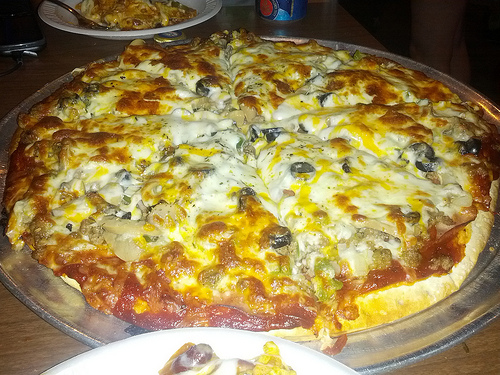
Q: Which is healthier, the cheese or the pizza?
A: The cheese is healthier than the pizza.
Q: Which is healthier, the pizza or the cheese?
A: The cheese is healthier than the pizza.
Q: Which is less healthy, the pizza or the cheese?
A: The pizza is less healthy than the cheese.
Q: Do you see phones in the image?
A: Yes, there is a phone.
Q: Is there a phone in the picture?
A: Yes, there is a phone.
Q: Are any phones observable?
A: Yes, there is a phone.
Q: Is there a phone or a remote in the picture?
A: Yes, there is a phone.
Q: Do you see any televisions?
A: No, there are no televisions.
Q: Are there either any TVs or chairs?
A: No, there are no TVs or chairs.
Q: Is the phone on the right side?
A: No, the phone is on the left of the image.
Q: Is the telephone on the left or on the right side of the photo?
A: The telephone is on the left of the image.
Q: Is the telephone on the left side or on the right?
A: The telephone is on the left of the image.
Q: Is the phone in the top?
A: Yes, the phone is in the top of the image.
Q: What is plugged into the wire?
A: The telephone is plugged into the wire.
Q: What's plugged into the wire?
A: The telephone is plugged into the wire.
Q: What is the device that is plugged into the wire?
A: The device is a phone.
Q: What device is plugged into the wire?
A: The device is a phone.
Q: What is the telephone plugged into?
A: The telephone is plugged into the wire.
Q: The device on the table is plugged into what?
A: The telephone is plugged into the wire.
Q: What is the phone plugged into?
A: The telephone is plugged into the wire.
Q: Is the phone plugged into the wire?
A: Yes, the phone is plugged into the wire.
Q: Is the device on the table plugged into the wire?
A: Yes, the phone is plugged into the wire.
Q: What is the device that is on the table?
A: The device is a phone.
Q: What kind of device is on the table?
A: The device is a phone.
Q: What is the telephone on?
A: The telephone is on the table.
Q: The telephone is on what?
A: The telephone is on the table.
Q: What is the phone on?
A: The telephone is on the table.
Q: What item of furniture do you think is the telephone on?
A: The telephone is on the table.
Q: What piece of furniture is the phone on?
A: The telephone is on the table.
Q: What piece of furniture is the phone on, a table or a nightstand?
A: The phone is on a table.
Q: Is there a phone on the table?
A: Yes, there is a phone on the table.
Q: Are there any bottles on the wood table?
A: No, there is a phone on the table.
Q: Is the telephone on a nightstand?
A: No, the telephone is on the table.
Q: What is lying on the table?
A: The phone is lying on the table.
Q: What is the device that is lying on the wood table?
A: The device is a phone.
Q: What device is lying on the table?
A: The device is a phone.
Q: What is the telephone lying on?
A: The telephone is lying on the table.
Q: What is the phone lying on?
A: The telephone is lying on the table.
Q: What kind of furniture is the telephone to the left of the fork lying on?
A: The telephone is lying on the table.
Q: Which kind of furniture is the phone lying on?
A: The telephone is lying on the table.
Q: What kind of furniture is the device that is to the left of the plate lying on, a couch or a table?
A: The phone is lying on a table.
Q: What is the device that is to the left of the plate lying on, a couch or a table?
A: The phone is lying on a table.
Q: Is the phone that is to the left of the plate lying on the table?
A: Yes, the telephone is lying on the table.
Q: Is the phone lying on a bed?
A: No, the phone is lying on the table.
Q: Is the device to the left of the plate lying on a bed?
A: No, the phone is lying on the table.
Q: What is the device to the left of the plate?
A: The device is a phone.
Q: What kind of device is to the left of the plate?
A: The device is a phone.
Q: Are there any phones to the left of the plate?
A: Yes, there is a phone to the left of the plate.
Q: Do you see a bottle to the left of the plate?
A: No, there is a phone to the left of the plate.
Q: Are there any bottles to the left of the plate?
A: No, there is a phone to the left of the plate.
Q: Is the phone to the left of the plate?
A: Yes, the phone is to the left of the plate.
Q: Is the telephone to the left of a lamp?
A: No, the telephone is to the left of the plate.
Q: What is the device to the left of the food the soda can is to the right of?
A: The device is a phone.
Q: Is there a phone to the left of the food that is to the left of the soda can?
A: Yes, there is a phone to the left of the food.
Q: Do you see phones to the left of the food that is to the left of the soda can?
A: Yes, there is a phone to the left of the food.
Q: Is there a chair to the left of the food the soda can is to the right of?
A: No, there is a phone to the left of the food.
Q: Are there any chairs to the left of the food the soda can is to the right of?
A: No, there is a phone to the left of the food.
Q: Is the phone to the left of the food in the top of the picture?
A: Yes, the phone is to the left of the food.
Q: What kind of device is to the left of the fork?
A: The device is a phone.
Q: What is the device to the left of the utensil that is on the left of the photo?
A: The device is a phone.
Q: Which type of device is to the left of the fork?
A: The device is a phone.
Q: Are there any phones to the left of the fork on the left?
A: Yes, there is a phone to the left of the fork.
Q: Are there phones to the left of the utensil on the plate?
A: Yes, there is a phone to the left of the fork.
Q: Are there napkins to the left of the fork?
A: No, there is a phone to the left of the fork.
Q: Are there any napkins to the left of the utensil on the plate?
A: No, there is a phone to the left of the fork.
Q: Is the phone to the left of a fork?
A: Yes, the phone is to the left of a fork.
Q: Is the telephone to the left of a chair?
A: No, the telephone is to the left of a fork.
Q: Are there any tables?
A: Yes, there is a table.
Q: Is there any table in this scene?
A: Yes, there is a table.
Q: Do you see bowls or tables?
A: Yes, there is a table.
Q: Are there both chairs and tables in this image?
A: No, there is a table but no chairs.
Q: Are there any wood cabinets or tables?
A: Yes, there is a wood table.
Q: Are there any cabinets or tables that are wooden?
A: Yes, the table is wooden.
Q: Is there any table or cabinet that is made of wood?
A: Yes, the table is made of wood.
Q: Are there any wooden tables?
A: Yes, there is a wood table.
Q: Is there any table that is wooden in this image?
A: Yes, there is a wood table.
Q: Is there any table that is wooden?
A: Yes, there is a table that is wooden.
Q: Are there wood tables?
A: Yes, there is a table that is made of wood.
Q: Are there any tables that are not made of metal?
A: Yes, there is a table that is made of wood.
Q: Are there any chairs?
A: No, there are no chairs.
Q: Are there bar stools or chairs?
A: No, there are no chairs or bar stools.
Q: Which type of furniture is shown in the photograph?
A: The furniture is a table.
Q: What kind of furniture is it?
A: The piece of furniture is a table.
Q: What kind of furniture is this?
A: That is a table.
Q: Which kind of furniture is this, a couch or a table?
A: That is a table.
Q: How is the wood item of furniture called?
A: The piece of furniture is a table.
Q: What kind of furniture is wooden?
A: The furniture is a table.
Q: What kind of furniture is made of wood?
A: The furniture is a table.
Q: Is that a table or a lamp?
A: That is a table.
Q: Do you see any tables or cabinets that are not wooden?
A: No, there is a table but it is wooden.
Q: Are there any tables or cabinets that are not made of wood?
A: No, there is a table but it is made of wood.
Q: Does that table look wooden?
A: Yes, the table is wooden.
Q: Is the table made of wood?
A: Yes, the table is made of wood.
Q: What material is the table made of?
A: The table is made of wood.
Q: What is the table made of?
A: The table is made of wood.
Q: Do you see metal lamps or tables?
A: No, there is a table but it is wooden.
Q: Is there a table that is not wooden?
A: No, there is a table but it is wooden.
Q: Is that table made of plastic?
A: No, the table is made of wood.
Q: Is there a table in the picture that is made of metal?
A: No, there is a table but it is made of wood.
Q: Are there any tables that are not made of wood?
A: No, there is a table but it is made of wood.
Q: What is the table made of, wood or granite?
A: The table is made of wood.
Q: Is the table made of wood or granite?
A: The table is made of wood.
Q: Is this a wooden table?
A: Yes, this is a wooden table.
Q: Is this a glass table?
A: No, this is a wooden table.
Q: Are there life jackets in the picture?
A: No, there are no life jackets.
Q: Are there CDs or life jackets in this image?
A: No, there are no life jackets or cds.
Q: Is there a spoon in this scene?
A: No, there are no spoons.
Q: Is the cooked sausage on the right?
A: Yes, the sausage is on the right of the image.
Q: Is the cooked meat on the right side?
A: Yes, the sausage is on the right of the image.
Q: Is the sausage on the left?
A: No, the sausage is on the right of the image.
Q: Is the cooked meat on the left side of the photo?
A: No, the sausage is on the right of the image.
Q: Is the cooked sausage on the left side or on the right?
A: The sausage is on the right of the image.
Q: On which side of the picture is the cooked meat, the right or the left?
A: The sausage is on the right of the image.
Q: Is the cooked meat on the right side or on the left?
A: The sausage is on the right of the image.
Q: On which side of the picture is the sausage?
A: The sausage is on the right of the image.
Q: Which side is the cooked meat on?
A: The sausage is on the right of the image.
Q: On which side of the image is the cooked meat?
A: The sausage is on the right of the image.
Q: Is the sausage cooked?
A: Yes, the sausage is cooked.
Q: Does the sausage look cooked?
A: Yes, the sausage is cooked.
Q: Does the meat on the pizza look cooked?
A: Yes, the sausage is cooked.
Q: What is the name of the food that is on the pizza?
A: The food is a sausage.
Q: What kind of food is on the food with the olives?
A: The food is a sausage.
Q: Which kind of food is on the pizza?
A: The food is a sausage.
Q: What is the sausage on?
A: The sausage is on the pizza.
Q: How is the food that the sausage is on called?
A: The food is a pizza.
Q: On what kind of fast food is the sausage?
A: The sausage is on the pizza.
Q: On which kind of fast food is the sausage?
A: The sausage is on the pizza.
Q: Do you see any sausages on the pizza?
A: Yes, there is a sausage on the pizza.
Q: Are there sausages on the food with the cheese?
A: Yes, there is a sausage on the pizza.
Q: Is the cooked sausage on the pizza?
A: Yes, the sausage is on the pizza.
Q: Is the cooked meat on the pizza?
A: Yes, the sausage is on the pizza.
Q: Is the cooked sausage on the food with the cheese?
A: Yes, the sausage is on the pizza.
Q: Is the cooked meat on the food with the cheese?
A: Yes, the sausage is on the pizza.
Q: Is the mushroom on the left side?
A: Yes, the mushroom is on the left of the image.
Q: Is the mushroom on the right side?
A: No, the mushroom is on the left of the image.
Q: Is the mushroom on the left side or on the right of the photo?
A: The mushroom is on the left of the image.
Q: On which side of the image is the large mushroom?
A: The mushroom is on the left of the image.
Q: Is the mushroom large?
A: Yes, the mushroom is large.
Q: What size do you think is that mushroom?
A: The mushroom is large.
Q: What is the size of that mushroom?
A: The mushroom is large.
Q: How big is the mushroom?
A: The mushroom is large.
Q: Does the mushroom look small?
A: No, the mushroom is large.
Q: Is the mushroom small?
A: No, the mushroom is large.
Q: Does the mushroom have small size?
A: No, the mushroom is large.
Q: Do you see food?
A: Yes, there is food.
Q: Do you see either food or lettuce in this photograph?
A: Yes, there is food.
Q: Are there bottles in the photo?
A: No, there are no bottles.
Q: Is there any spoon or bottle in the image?
A: No, there are no bottles or spoons.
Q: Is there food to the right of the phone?
A: Yes, there is food to the right of the phone.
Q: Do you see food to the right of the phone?
A: Yes, there is food to the right of the phone.